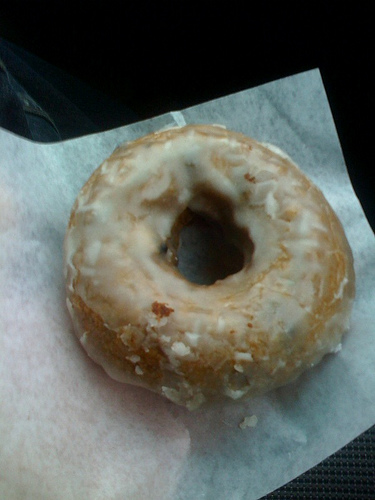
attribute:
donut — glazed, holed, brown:
[53, 132, 366, 407]